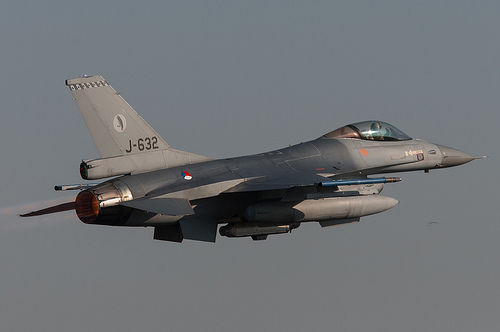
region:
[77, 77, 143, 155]
Tail of jet is gray.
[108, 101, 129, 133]
White circle on tail of plane.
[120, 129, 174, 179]
Black writing on tail of jet.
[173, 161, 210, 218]
Red, white, and blue marking on rear of jet.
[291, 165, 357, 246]
Weapons on side of jet.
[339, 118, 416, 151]
Clear hatch on front of jet.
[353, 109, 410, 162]
Person sitting inside of jet.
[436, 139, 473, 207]
Front end of jet is gray.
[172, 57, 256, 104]
Sky is grayish blue.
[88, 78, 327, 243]
Jet is flying in sky.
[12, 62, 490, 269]
an aircraft flying in the sky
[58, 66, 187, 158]
fin of aircraft has number J-632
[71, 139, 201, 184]
engine of aircraft over a wing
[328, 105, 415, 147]
a window over pilot seat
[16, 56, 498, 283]
a military aircraft flies on the sky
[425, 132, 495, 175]
nose of jet is pointy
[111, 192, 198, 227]
right vertical fin of aircraft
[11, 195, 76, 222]
left vertical fin of aircraft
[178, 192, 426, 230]
a weapon under military aircraft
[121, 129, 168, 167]
letters are black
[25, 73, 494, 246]
a jet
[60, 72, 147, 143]
tail of the jet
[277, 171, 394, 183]
wing of the jet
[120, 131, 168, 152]
numbers on the jet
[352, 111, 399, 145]
a driver of the jet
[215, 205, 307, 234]
a shadow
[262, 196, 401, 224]
a missel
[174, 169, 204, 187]
a logo on the jet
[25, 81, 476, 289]
the jet is flying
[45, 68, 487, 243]
jet is in the sky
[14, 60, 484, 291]
a fighter jet in a gray sky.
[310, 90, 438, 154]
a cockpit on a fighter jet.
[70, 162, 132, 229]
a jet engine on a jet.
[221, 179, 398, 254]
a fuel tank under a jet.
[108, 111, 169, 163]
a serial number on a fighter jet.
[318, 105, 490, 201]
a front end of a fighter jet.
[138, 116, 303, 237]
the center of a fighter jet.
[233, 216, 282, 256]
landing gear under a jet.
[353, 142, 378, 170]
a red spot of paint.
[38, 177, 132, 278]
a glowing red jet engine.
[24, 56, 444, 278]
jet in the air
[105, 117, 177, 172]
numbers on the plane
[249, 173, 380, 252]
wing of the plane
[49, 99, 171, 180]
tail of the plane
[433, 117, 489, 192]
nose of the plane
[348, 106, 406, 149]
cockpit of the plane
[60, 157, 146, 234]
back of the plane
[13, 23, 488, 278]
silver plane in sky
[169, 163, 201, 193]
red, white and blue symbol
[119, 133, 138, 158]
the letter J